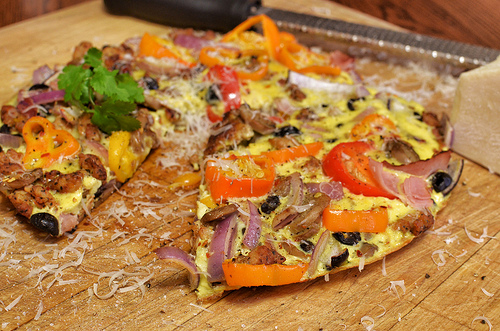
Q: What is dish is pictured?
A: Pizza.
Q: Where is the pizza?
A: On a board.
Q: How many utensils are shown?
A: One.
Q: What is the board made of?
A: Wood.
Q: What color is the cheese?
A: White.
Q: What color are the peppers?
A: Orange.